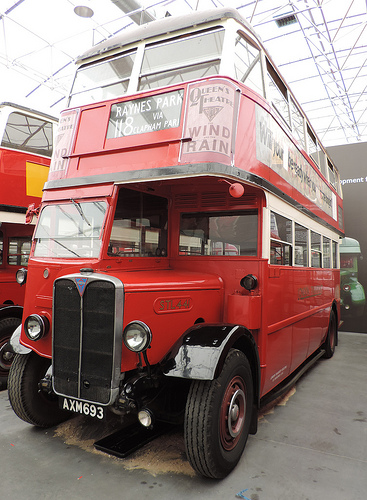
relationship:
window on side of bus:
[317, 234, 344, 271] [7, 6, 344, 481]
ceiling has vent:
[3, 4, 365, 148] [274, 12, 300, 30]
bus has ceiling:
[7, 6, 344, 481] [3, 4, 365, 148]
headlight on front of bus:
[19, 310, 52, 343] [7, 6, 344, 481]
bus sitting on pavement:
[7, 6, 344, 481] [0, 330, 365, 498]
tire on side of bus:
[319, 305, 349, 352] [4, 6, 355, 350]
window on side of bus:
[268, 208, 293, 265] [7, 6, 344, 481]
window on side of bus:
[293, 218, 309, 270] [7, 6, 344, 481]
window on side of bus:
[307, 225, 322, 271] [7, 6, 344, 481]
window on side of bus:
[322, 234, 332, 267] [7, 6, 344, 481]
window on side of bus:
[331, 239, 336, 267] [7, 6, 344, 481]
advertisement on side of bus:
[261, 143, 337, 207] [13, 24, 346, 346]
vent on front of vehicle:
[35, 269, 132, 341] [36, 86, 316, 337]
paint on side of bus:
[28, 163, 44, 198] [3, 98, 63, 381]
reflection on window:
[31, 195, 114, 265] [31, 195, 113, 265]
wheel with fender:
[182, 343, 272, 482] [180, 325, 224, 372]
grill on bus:
[49, 270, 126, 407] [7, 6, 344, 481]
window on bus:
[268, 208, 293, 265] [7, 6, 344, 481]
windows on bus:
[234, 29, 342, 198] [7, 6, 344, 481]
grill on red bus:
[49, 270, 126, 407] [6, 7, 344, 482]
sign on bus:
[175, 77, 242, 167] [7, 6, 344, 481]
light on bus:
[133, 406, 156, 429] [55, 27, 298, 445]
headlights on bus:
[23, 312, 153, 368] [7, 6, 344, 481]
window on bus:
[30, 196, 109, 259] [7, 6, 344, 481]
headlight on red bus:
[116, 321, 155, 356] [27, 140, 296, 433]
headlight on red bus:
[23, 313, 50, 341] [27, 140, 296, 433]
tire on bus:
[174, 344, 254, 484] [7, 6, 344, 481]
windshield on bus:
[178, 210, 259, 256] [7, 6, 344, 481]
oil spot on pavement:
[141, 478, 176, 489] [0, 332, 367, 498]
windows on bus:
[268, 209, 340, 272] [14, 36, 341, 464]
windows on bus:
[236, 29, 340, 182] [14, 36, 341, 464]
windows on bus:
[67, 29, 218, 106] [14, 36, 341, 464]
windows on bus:
[37, 202, 102, 257] [14, 36, 341, 464]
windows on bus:
[177, 209, 256, 254] [14, 36, 341, 464]